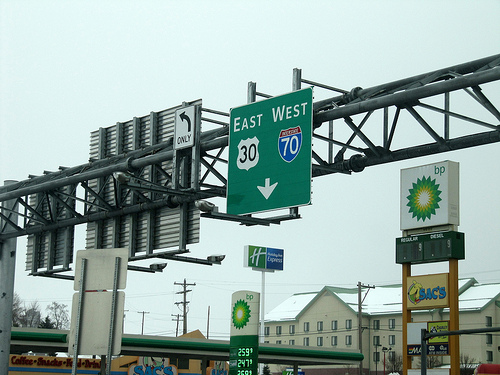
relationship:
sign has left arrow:
[172, 104, 195, 149] [178, 109, 191, 132]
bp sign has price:
[228, 289, 260, 374] [236, 347, 254, 358]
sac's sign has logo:
[404, 273, 447, 310] [407, 281, 445, 304]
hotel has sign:
[259, 276, 498, 375] [243, 244, 284, 273]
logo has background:
[230, 299, 251, 330] [230, 290, 259, 336]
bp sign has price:
[228, 289, 260, 374] [237, 358, 252, 367]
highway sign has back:
[84, 99, 225, 273] [86, 97, 202, 252]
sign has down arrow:
[226, 86, 314, 217] [254, 177, 277, 202]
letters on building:
[10, 353, 103, 370] [10, 329, 228, 375]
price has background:
[236, 347, 254, 358] [228, 335, 259, 374]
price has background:
[237, 358, 252, 367] [228, 335, 259, 374]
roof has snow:
[260, 277, 499, 323] [264, 291, 319, 322]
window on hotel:
[330, 319, 338, 333] [259, 276, 498, 375]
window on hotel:
[316, 321, 324, 332] [259, 276, 498, 375]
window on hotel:
[302, 320, 310, 333] [259, 276, 498, 375]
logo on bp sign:
[230, 299, 251, 330] [228, 289, 260, 374]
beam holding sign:
[0, 52, 497, 242] [226, 86, 314, 217]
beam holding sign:
[0, 52, 497, 242] [172, 104, 195, 149]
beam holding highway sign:
[0, 52, 497, 242] [84, 99, 225, 273]